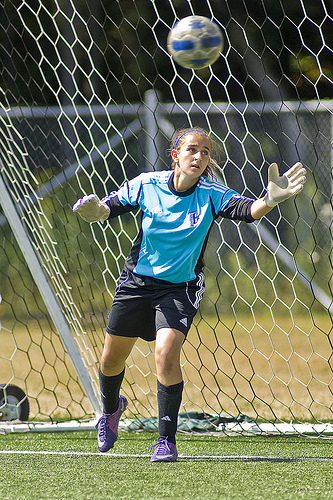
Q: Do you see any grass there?
A: Yes, there is grass.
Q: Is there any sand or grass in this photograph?
A: Yes, there is grass.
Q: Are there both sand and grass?
A: No, there is grass but no sand.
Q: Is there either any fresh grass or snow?
A: Yes, there is fresh grass.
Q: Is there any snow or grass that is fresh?
A: Yes, the grass is fresh.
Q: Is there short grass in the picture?
A: Yes, there is short grass.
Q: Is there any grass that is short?
A: Yes, there is grass that is short.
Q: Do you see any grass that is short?
A: Yes, there is grass that is short.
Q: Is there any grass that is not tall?
A: Yes, there is short grass.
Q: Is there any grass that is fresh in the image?
A: Yes, there is fresh grass.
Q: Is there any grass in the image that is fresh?
A: Yes, there is grass that is fresh.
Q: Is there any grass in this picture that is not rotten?
A: Yes, there is fresh grass.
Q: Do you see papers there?
A: No, there are no papers.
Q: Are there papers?
A: No, there are no papers.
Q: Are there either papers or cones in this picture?
A: No, there are no papers or cones.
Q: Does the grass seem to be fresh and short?
A: Yes, the grass is fresh and short.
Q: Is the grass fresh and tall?
A: No, the grass is fresh but short.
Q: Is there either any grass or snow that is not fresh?
A: No, there is grass but it is fresh.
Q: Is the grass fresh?
A: Yes, the grass is fresh.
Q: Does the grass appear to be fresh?
A: Yes, the grass is fresh.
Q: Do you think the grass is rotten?
A: No, the grass is fresh.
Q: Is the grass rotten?
A: No, the grass is fresh.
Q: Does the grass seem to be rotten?
A: No, the grass is fresh.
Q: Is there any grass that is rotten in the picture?
A: No, there is grass but it is fresh.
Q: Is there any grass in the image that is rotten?
A: No, there is grass but it is fresh.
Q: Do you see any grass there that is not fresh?
A: No, there is grass but it is fresh.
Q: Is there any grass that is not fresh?
A: No, there is grass but it is fresh.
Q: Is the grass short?
A: Yes, the grass is short.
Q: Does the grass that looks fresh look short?
A: Yes, the grass is short.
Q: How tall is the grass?
A: The grass is short.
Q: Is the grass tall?
A: No, the grass is short.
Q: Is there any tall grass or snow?
A: No, there is grass but it is short.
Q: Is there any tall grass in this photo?
A: No, there is grass but it is short.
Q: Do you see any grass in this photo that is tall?
A: No, there is grass but it is short.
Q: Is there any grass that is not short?
A: No, there is grass but it is short.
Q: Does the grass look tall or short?
A: The grass is short.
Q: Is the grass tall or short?
A: The grass is short.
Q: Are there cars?
A: No, there are no cars.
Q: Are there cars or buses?
A: No, there are no cars or buses.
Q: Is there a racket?
A: No, there are no rackets.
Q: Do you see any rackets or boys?
A: No, there are no rackets or boys.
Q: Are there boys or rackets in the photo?
A: No, there are no rackets or boys.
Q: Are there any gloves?
A: Yes, there are gloves.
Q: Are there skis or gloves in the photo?
A: Yes, there are gloves.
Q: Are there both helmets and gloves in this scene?
A: No, there are gloves but no helmets.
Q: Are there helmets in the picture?
A: No, there are no helmets.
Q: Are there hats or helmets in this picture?
A: No, there are no helmets or hats.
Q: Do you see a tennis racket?
A: No, there are no rackets.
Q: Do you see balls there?
A: Yes, there is a ball.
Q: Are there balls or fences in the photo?
A: Yes, there is a ball.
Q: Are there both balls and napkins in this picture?
A: No, there is a ball but no napkins.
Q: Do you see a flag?
A: No, there are no flags.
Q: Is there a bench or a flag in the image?
A: No, there are no flags or benches.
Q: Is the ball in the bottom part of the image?
A: No, the ball is in the top of the image.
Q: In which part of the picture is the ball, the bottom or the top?
A: The ball is in the top of the image.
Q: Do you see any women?
A: Yes, there is a woman.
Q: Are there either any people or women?
A: Yes, there is a woman.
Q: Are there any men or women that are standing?
A: Yes, the woman is standing.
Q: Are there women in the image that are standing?
A: Yes, there is a woman that is standing.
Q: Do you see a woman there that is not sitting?
A: Yes, there is a woman that is standing .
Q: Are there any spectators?
A: No, there are no spectators.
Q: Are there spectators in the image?
A: No, there are no spectators.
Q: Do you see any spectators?
A: No, there are no spectators.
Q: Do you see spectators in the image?
A: No, there are no spectators.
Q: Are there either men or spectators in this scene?
A: No, there are no spectators or men.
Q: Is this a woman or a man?
A: This is a woman.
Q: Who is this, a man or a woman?
A: This is a woman.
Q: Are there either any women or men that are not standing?
A: No, there is a woman but she is standing.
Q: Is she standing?
A: Yes, the woman is standing.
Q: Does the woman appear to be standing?
A: Yes, the woman is standing.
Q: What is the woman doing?
A: The woman is standing.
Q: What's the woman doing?
A: The woman is standing.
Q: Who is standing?
A: The woman is standing.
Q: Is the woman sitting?
A: No, the woman is standing.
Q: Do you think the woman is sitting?
A: No, the woman is standing.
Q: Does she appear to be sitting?
A: No, the woman is standing.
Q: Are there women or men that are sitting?
A: No, there is a woman but she is standing.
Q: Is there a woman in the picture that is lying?
A: No, there is a woman but she is standing.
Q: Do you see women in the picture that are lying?
A: No, there is a woman but she is standing.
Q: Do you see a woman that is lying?
A: No, there is a woman but she is standing.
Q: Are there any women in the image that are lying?
A: No, there is a woman but she is standing.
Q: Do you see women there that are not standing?
A: No, there is a woman but she is standing.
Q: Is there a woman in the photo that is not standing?
A: No, there is a woman but she is standing.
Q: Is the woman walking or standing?
A: The woman is standing.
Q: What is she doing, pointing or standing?
A: The woman is standing.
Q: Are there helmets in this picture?
A: No, there are no helmets.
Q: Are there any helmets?
A: No, there are no helmets.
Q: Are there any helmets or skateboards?
A: No, there are no helmets or skateboards.